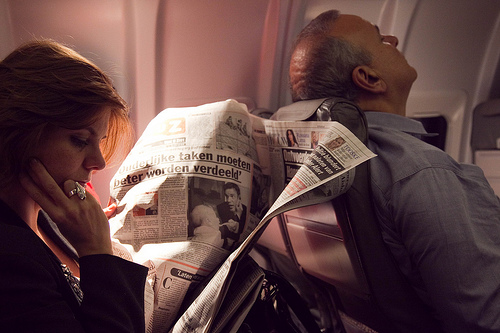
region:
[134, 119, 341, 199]
a newspaper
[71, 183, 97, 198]
women wearing a ring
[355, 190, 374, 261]
a seat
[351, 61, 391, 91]
a man ear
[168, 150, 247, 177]
writing in the newspaper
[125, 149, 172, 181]
light on the newspaper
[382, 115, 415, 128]
a collard shirt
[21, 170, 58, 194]
the womens finger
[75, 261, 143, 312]
a sleeve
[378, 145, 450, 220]
the man is wearing a grey shirt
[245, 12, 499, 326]
a man sleeping on a airplane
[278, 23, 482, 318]
a man sleeping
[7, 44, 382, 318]
a woman reading a newspaper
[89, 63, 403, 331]
a newspaper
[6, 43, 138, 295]
a woman wearing a ring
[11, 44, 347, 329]
a woman sitting down on a airplane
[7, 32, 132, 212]
a woman with red hair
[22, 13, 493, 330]
two people on a airplane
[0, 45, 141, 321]
a woman wearing a black jacket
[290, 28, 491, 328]
a man wearing a long sleeve shirt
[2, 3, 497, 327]
woman and man inside an airplane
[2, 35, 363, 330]
a woman reading a newspaper inside an airplane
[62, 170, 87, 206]
a big ring on a woman's ring finger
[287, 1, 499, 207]
man sleeping on a flight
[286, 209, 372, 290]
the back of a seat on an airplane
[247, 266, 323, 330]
part of a woman's pocket book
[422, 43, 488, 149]
corner of a window inside a flight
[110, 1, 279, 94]
the inside wall of an aeroplane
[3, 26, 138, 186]
woman's red hair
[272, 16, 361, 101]
the top of a man's balding head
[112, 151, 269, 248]
Bold headline in newspaper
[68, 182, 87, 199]
Ring on woman's finger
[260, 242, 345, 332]
Black bag in woman's lap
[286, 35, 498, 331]
Man in gray shirt sleeping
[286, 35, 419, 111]
Man's head resting on back of chair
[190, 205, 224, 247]
Picture of baby in article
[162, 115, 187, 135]
Orange logo on newspaper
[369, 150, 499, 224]
Wrinkles on shoulder of shirt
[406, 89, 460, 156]
Small window on side of wall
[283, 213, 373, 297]
Pocket in back of seat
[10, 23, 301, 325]
a woman on a plane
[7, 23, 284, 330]
a woman on an airplane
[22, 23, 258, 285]
a woman sitting on a plane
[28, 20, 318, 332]
a woman sitting on an airplane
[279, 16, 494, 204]
a man on a plane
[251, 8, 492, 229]
a man on an airplane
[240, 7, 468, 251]
a man sleeping on a plane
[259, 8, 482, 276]
a mans sleeping on an airplane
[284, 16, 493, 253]
a man sitting on a plane